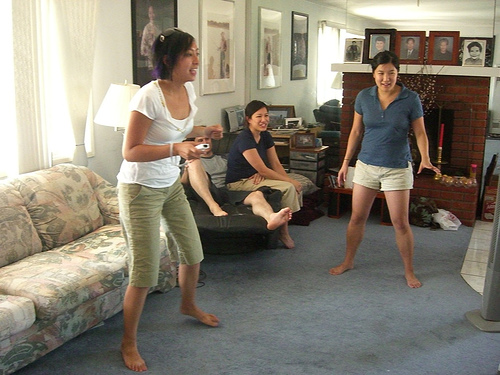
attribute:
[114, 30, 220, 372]
woman — young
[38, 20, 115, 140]
curtain — white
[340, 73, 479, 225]
fireplace — red, brick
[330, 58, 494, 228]
fireplace — central, tiled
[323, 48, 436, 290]
woman — young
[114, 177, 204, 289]
pants — light green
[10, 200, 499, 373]
carpet — grey, blue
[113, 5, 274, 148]
hair — black and purple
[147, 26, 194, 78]
hair — dark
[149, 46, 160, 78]
streak — purple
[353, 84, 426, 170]
shirt — blue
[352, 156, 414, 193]
shorts — white